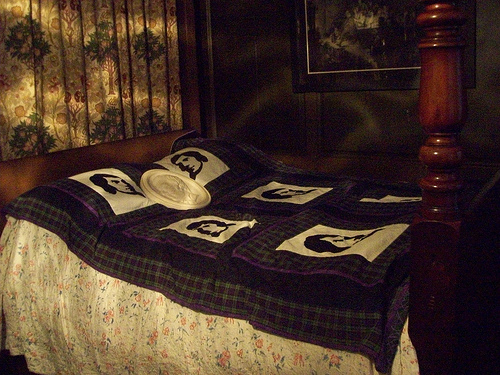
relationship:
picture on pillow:
[68, 168, 153, 212] [6, 162, 168, 230]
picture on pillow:
[154, 147, 231, 187] [157, 131, 279, 195]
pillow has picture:
[6, 162, 168, 230] [68, 168, 153, 212]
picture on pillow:
[68, 168, 153, 212] [157, 131, 279, 195]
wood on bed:
[411, 1, 472, 374] [1, 130, 422, 374]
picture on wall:
[288, 1, 423, 92] [195, 1, 291, 143]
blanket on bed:
[16, 129, 415, 374] [1, 130, 422, 374]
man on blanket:
[172, 148, 212, 180] [16, 129, 415, 374]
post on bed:
[409, 1, 468, 369] [1, 130, 422, 374]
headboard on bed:
[410, 166, 498, 373] [1, 130, 422, 374]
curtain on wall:
[1, 1, 187, 159] [195, 1, 291, 143]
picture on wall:
[304, 1, 425, 74] [195, 1, 291, 143]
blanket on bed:
[1, 237, 87, 373] [1, 130, 422, 374]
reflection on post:
[432, 136, 441, 158] [409, 1, 468, 369]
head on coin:
[156, 175, 200, 202] [139, 164, 211, 210]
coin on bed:
[139, 164, 211, 210] [1, 130, 422, 374]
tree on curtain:
[84, 19, 125, 98] [1, 1, 187, 159]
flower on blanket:
[216, 347, 233, 369] [1, 237, 87, 373]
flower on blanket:
[100, 307, 117, 324] [1, 237, 87, 373]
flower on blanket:
[76, 259, 90, 271] [1, 237, 87, 373]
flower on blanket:
[288, 351, 308, 369] [1, 237, 87, 373]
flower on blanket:
[18, 241, 30, 258] [1, 237, 87, 373]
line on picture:
[303, 1, 313, 77] [304, 1, 425, 74]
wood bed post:
[411, 1, 472, 374] [409, 1, 468, 369]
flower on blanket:
[143, 325, 176, 357] [1, 237, 87, 373]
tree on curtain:
[130, 24, 166, 63] [1, 1, 187, 159]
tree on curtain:
[5, 15, 50, 67] [1, 1, 187, 159]